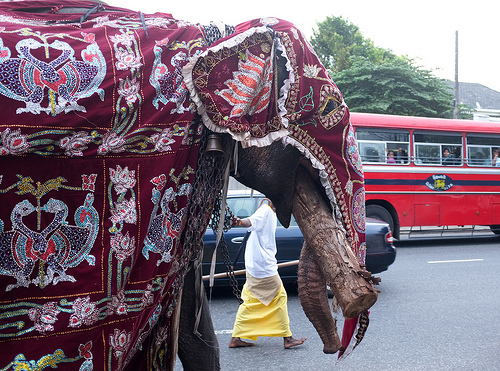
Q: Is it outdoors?
A: Yes, it is outdoors.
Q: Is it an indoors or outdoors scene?
A: It is outdoors.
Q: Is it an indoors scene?
A: No, it is outdoors.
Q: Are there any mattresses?
A: No, there are no mattresses.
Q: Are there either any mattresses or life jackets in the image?
A: No, there are no mattresses or life jackets.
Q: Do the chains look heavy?
A: Yes, the chains are heavy.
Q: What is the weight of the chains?
A: The chains are heavy.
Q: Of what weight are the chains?
A: The chains are heavy.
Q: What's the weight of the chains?
A: The chains are heavy.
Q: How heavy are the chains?
A: The chains are heavy.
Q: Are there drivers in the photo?
A: No, there are no drivers.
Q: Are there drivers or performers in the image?
A: No, there are no drivers or performers.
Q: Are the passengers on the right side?
A: Yes, the passengers are on the right of the image.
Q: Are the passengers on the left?
A: No, the passengers are on the right of the image.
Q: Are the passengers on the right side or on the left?
A: The passengers are on the right of the image.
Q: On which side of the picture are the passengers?
A: The passengers are on the right of the image.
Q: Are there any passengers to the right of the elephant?
A: Yes, there are passengers to the right of the elephant.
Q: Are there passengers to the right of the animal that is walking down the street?
A: Yes, there are passengers to the right of the elephant.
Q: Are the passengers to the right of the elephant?
A: Yes, the passengers are to the right of the elephant.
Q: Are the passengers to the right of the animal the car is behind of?
A: Yes, the passengers are to the right of the elephant.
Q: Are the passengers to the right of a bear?
A: No, the passengers are to the right of the elephant.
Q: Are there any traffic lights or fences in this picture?
A: No, there are no fences or traffic lights.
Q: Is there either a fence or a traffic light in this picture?
A: No, there are no fences or traffic lights.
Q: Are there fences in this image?
A: No, there are no fences.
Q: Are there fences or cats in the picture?
A: No, there are no fences or cats.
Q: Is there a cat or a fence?
A: No, there are no fences or cats.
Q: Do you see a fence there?
A: No, there are no fences.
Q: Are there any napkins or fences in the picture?
A: No, there are no fences or napkins.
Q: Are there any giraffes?
A: No, there are no giraffes.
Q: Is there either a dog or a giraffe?
A: No, there are no giraffes or dogs.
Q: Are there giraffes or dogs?
A: No, there are no giraffes or dogs.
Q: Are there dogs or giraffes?
A: No, there are no giraffes or dogs.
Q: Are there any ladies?
A: No, there are no ladies.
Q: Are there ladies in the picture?
A: No, there are no ladies.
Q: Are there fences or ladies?
A: No, there are no ladies or fences.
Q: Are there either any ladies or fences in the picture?
A: No, there are no ladies or fences.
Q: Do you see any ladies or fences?
A: No, there are no ladies or fences.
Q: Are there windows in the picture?
A: Yes, there is a window.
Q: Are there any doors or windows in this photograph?
A: Yes, there is a window.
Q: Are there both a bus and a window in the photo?
A: Yes, there are both a window and a bus.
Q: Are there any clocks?
A: No, there are no clocks.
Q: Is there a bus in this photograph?
A: Yes, there is a bus.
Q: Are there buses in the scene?
A: Yes, there is a bus.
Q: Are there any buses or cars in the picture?
A: Yes, there is a bus.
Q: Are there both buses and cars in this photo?
A: Yes, there are both a bus and a car.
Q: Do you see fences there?
A: No, there are no fences.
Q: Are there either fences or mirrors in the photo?
A: No, there are no fences or mirrors.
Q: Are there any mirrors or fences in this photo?
A: No, there are no fences or mirrors.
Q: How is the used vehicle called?
A: The vehicle is a bus.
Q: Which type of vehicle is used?
A: The vehicle is a bus.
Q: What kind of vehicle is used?
A: The vehicle is a bus.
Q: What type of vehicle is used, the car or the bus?
A: The bus is used.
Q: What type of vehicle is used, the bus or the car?
A: The bus is used.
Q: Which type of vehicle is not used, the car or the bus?
A: The car is not used.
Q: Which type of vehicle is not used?
A: The vehicle is a car.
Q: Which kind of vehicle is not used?
A: The vehicle is a car.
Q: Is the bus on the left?
A: No, the bus is on the right of the image.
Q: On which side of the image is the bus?
A: The bus is on the right of the image.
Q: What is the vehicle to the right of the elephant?
A: The vehicle is a bus.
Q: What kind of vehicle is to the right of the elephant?
A: The vehicle is a bus.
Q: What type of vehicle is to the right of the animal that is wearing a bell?
A: The vehicle is a bus.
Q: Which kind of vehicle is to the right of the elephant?
A: The vehicle is a bus.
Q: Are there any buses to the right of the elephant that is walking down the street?
A: Yes, there is a bus to the right of the elephant.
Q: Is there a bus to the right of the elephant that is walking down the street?
A: Yes, there is a bus to the right of the elephant.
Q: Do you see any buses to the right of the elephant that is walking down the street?
A: Yes, there is a bus to the right of the elephant.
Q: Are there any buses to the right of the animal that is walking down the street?
A: Yes, there is a bus to the right of the elephant.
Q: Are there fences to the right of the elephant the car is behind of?
A: No, there is a bus to the right of the elephant.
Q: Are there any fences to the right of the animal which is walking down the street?
A: No, there is a bus to the right of the elephant.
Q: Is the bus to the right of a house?
A: No, the bus is to the right of the elephant.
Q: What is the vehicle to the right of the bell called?
A: The vehicle is a bus.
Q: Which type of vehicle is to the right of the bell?
A: The vehicle is a bus.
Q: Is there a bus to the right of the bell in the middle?
A: Yes, there is a bus to the right of the bell.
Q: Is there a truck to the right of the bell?
A: No, there is a bus to the right of the bell.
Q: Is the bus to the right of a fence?
A: No, the bus is to the right of the bell.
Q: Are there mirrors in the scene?
A: No, there are no mirrors.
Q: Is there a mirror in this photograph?
A: No, there are no mirrors.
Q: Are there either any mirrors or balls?
A: No, there are no mirrors or balls.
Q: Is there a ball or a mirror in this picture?
A: No, there are no mirrors or balls.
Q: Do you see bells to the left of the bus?
A: Yes, there is a bell to the left of the bus.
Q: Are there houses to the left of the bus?
A: No, there is a bell to the left of the bus.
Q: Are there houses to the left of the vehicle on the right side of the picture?
A: No, there is a bell to the left of the bus.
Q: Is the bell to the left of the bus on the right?
A: Yes, the bell is to the left of the bus.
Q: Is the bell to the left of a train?
A: No, the bell is to the left of the bus.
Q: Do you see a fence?
A: No, there are no fences.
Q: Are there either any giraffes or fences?
A: No, there are no fences or giraffes.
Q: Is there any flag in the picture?
A: No, there are no flags.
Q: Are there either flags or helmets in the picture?
A: No, there are no flags or helmets.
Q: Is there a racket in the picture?
A: No, there are no rackets.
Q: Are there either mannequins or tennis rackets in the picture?
A: No, there are no tennis rackets or mannequins.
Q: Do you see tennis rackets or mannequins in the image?
A: No, there are no tennis rackets or mannequins.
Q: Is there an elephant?
A: Yes, there is an elephant.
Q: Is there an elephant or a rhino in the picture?
A: Yes, there is an elephant.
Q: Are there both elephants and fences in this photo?
A: No, there is an elephant but no fences.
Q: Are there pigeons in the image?
A: No, there are no pigeons.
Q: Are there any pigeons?
A: No, there are no pigeons.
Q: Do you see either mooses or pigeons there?
A: No, there are no pigeons or mooses.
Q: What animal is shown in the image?
A: The animal is an elephant.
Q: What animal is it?
A: The animal is an elephant.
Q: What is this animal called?
A: This is an elephant.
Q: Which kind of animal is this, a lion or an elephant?
A: This is an elephant.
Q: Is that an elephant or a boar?
A: That is an elephant.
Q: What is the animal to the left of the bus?
A: The animal is an elephant.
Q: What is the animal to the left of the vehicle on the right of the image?
A: The animal is an elephant.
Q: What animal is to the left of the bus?
A: The animal is an elephant.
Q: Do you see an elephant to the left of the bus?
A: Yes, there is an elephant to the left of the bus.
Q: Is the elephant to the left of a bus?
A: Yes, the elephant is to the left of a bus.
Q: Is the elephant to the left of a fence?
A: No, the elephant is to the left of a bus.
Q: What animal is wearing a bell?
A: The elephant is wearing a bell.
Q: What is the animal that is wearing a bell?
A: The animal is an elephant.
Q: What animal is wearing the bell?
A: The animal is an elephant.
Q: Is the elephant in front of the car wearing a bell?
A: Yes, the elephant is wearing a bell.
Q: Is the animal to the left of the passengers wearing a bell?
A: Yes, the elephant is wearing a bell.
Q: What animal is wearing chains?
A: The elephant is wearing chains.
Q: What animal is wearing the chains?
A: The elephant is wearing chains.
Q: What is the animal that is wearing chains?
A: The animal is an elephant.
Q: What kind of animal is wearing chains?
A: The animal is an elephant.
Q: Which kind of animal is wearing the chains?
A: The animal is an elephant.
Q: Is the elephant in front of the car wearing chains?
A: Yes, the elephant is wearing chains.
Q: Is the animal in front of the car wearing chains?
A: Yes, the elephant is wearing chains.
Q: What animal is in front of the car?
A: The elephant is in front of the car.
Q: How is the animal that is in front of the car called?
A: The animal is an elephant.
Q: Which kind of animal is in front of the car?
A: The animal is an elephant.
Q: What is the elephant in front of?
A: The elephant is in front of the car.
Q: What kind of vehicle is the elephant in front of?
A: The elephant is in front of the car.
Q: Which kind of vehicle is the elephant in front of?
A: The elephant is in front of the car.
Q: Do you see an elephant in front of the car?
A: Yes, there is an elephant in front of the car.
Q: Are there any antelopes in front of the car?
A: No, there is an elephant in front of the car.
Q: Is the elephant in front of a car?
A: Yes, the elephant is in front of a car.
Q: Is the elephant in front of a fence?
A: No, the elephant is in front of a car.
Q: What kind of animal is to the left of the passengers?
A: The animal is an elephant.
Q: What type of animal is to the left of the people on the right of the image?
A: The animal is an elephant.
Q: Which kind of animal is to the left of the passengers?
A: The animal is an elephant.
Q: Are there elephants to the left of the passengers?
A: Yes, there is an elephant to the left of the passengers.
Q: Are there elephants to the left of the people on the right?
A: Yes, there is an elephant to the left of the passengers.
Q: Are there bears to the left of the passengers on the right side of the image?
A: No, there is an elephant to the left of the passengers.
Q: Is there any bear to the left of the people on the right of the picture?
A: No, there is an elephant to the left of the passengers.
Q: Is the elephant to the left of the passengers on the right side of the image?
A: Yes, the elephant is to the left of the passengers.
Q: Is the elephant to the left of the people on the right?
A: Yes, the elephant is to the left of the passengers.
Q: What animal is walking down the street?
A: The elephant is walking down the street.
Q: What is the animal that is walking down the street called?
A: The animal is an elephant.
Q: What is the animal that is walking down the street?
A: The animal is an elephant.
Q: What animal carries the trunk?
A: The elephant carries the trunk.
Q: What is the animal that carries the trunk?
A: The animal is an elephant.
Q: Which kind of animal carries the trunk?
A: The animal is an elephant.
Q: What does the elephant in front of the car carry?
A: The elephant carries a trunk.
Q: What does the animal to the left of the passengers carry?
A: The elephant carries a trunk.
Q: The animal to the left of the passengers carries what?
A: The elephant carries a trunk.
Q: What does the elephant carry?
A: The elephant carries a trunk.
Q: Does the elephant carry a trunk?
A: Yes, the elephant carries a trunk.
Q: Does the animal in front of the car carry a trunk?
A: Yes, the elephant carries a trunk.